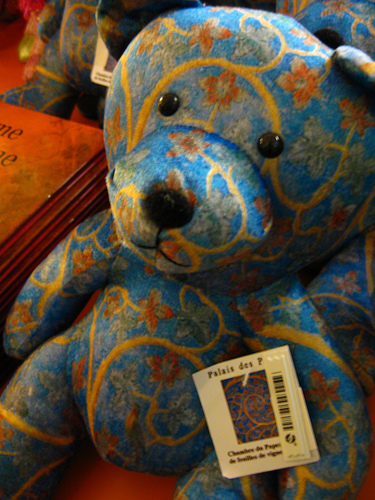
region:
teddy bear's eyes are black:
[137, 82, 285, 176]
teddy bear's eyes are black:
[156, 85, 282, 159]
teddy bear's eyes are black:
[138, 62, 280, 170]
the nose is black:
[133, 180, 201, 237]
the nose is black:
[139, 175, 185, 237]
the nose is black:
[138, 178, 189, 234]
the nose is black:
[139, 177, 207, 248]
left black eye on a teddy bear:
[257, 128, 285, 161]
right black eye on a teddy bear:
[154, 85, 184, 120]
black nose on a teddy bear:
[140, 183, 194, 232]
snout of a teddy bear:
[112, 116, 275, 270]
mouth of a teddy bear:
[125, 225, 188, 272]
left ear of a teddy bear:
[332, 38, 373, 104]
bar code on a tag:
[272, 369, 293, 434]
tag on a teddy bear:
[192, 343, 322, 483]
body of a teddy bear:
[71, 272, 237, 472]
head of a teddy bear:
[101, 9, 371, 294]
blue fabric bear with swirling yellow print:
[4, 4, 364, 489]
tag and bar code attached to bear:
[188, 341, 317, 476]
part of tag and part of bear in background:
[0, 0, 113, 125]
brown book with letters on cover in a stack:
[0, 78, 110, 303]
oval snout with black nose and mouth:
[101, 120, 270, 274]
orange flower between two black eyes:
[152, 56, 280, 161]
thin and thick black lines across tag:
[262, 351, 307, 456]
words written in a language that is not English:
[202, 348, 257, 381]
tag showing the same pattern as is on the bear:
[183, 295, 363, 490]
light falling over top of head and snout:
[105, 16, 367, 282]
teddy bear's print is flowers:
[53, 27, 298, 498]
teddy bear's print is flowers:
[49, 38, 348, 494]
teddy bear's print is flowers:
[45, 39, 348, 491]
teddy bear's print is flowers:
[45, 59, 353, 490]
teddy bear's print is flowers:
[118, 117, 370, 467]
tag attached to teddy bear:
[187, 325, 322, 494]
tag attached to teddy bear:
[167, 317, 322, 483]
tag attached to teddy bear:
[175, 332, 326, 482]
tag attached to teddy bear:
[178, 338, 323, 486]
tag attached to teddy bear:
[176, 324, 323, 484]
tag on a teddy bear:
[190, 339, 325, 476]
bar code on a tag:
[270, 364, 295, 432]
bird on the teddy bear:
[123, 396, 147, 468]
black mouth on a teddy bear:
[129, 224, 183, 269]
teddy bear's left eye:
[254, 127, 285, 162]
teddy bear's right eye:
[155, 90, 183, 118]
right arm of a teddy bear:
[3, 204, 124, 353]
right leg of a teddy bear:
[0, 323, 89, 498]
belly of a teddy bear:
[69, 284, 239, 475]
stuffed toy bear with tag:
[1, 1, 372, 498]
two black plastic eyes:
[157, 92, 282, 157]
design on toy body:
[71, 288, 237, 472]